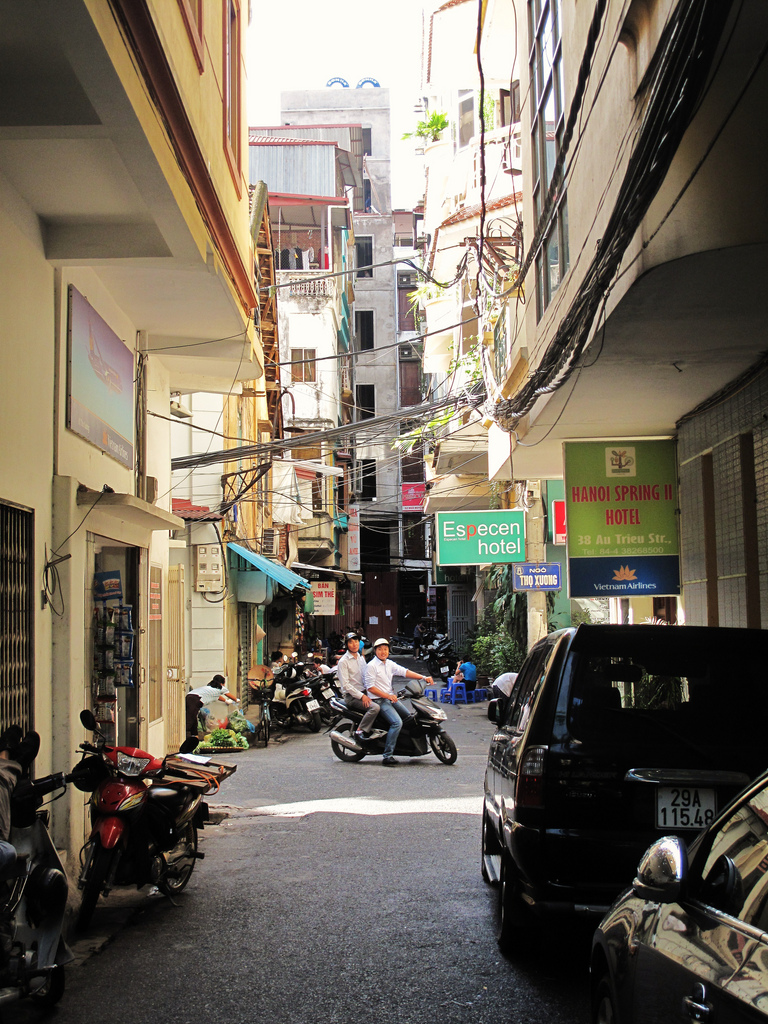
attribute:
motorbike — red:
[35, 748, 211, 862]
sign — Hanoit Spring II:
[538, 430, 698, 640]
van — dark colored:
[472, 630, 763, 827]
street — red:
[109, 625, 486, 1021]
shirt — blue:
[454, 657, 484, 684]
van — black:
[477, 614, 765, 935]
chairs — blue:
[421, 681, 487, 707]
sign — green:
[433, 500, 530, 574]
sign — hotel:
[558, 438, 673, 587]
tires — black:
[468, 820, 541, 964]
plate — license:
[645, 778, 721, 838]